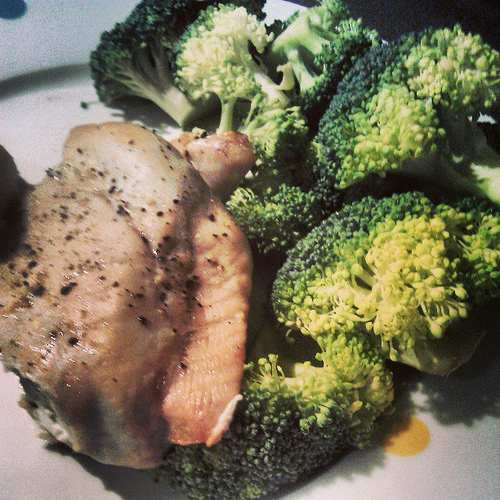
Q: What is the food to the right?
A: Broccoli.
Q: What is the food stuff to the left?
A: Meat.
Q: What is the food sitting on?
A: A plate.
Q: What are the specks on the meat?
A: Spice.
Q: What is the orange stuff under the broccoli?
A: Sauce.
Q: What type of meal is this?
A: Broccoli beef.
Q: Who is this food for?
A: A human.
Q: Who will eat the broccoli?
A: A human.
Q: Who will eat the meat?
A: A human.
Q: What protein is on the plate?
A: Meat.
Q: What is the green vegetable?
A: Broccoli.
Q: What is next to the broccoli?
A: Meat.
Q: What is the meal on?
A: A plate.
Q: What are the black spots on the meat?
A: Pepper.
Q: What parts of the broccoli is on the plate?
A: The flowerettes.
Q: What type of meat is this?
A: Pork.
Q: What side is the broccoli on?
A: The right.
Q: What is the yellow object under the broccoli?
A: A yellow dot on the plate.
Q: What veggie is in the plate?
A: Broccoli.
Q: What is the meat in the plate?
A: Chicken.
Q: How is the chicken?
A: Seasoned.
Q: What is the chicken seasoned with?
A: Black pepper.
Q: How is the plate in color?
A: White.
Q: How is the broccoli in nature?
A: Raw.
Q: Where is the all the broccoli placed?
A: Next to chicken.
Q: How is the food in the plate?
A: Edible.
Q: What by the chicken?
A: Broccoli.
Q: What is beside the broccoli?
A: Chicken.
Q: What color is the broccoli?
A: Green.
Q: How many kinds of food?
A: Two.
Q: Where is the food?
A: On a plate.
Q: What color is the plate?
A: White.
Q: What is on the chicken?
A: Seasoning.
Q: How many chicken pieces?
A: One.